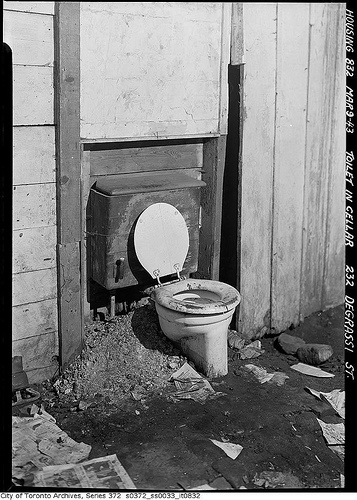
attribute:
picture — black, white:
[6, 10, 342, 483]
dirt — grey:
[46, 304, 215, 400]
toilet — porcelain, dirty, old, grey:
[91, 164, 241, 379]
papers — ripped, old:
[168, 356, 352, 460]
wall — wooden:
[248, 8, 342, 312]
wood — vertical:
[240, 4, 342, 174]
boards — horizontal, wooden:
[8, 1, 58, 168]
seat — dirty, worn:
[144, 277, 241, 315]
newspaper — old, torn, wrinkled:
[15, 413, 141, 488]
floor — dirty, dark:
[16, 390, 346, 485]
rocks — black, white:
[51, 357, 199, 422]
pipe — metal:
[104, 288, 116, 321]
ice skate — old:
[15, 359, 42, 406]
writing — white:
[330, 61, 354, 329]